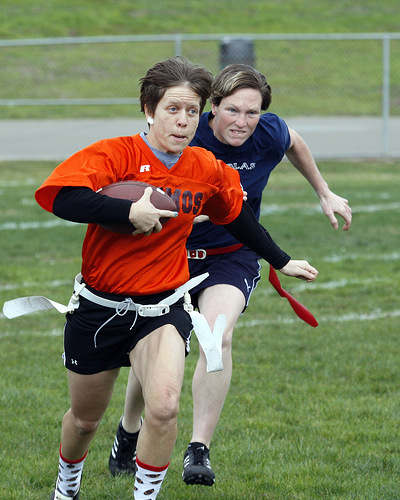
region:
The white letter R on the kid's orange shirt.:
[135, 162, 154, 170]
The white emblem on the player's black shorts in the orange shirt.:
[64, 354, 81, 368]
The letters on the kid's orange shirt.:
[155, 184, 209, 213]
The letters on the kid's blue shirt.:
[222, 164, 260, 172]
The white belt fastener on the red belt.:
[187, 246, 205, 261]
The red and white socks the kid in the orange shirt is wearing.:
[50, 439, 172, 499]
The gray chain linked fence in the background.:
[10, 37, 399, 126]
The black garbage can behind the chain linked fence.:
[209, 32, 273, 76]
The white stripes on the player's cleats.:
[107, 431, 215, 471]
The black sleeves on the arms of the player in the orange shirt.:
[53, 160, 283, 271]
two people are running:
[52, 62, 294, 498]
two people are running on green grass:
[11, 55, 378, 499]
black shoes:
[110, 397, 230, 491]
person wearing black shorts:
[45, 61, 255, 499]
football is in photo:
[80, 170, 183, 239]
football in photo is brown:
[90, 178, 186, 240]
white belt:
[11, 271, 219, 330]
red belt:
[187, 240, 328, 346]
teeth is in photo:
[226, 125, 247, 137]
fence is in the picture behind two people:
[3, 36, 399, 378]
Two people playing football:
[45, 41, 346, 461]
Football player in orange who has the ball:
[60, 52, 216, 344]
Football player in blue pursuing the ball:
[204, 44, 264, 272]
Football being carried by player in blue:
[84, 159, 189, 225]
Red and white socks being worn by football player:
[37, 442, 195, 496]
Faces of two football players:
[145, 85, 281, 142]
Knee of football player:
[147, 379, 181, 436]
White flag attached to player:
[183, 291, 233, 371]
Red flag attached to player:
[244, 244, 332, 329]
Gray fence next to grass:
[31, 31, 132, 99]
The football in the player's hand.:
[89, 178, 181, 230]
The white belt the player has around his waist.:
[73, 269, 201, 318]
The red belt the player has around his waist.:
[180, 241, 249, 261]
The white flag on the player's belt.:
[190, 310, 236, 370]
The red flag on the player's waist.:
[260, 257, 330, 331]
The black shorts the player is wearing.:
[58, 295, 204, 363]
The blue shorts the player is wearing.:
[183, 252, 267, 330]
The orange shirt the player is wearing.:
[66, 133, 227, 303]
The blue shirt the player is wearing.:
[183, 106, 280, 246]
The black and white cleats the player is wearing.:
[97, 419, 238, 485]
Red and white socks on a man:
[38, 439, 196, 499]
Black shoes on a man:
[106, 402, 238, 492]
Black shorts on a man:
[45, 267, 221, 376]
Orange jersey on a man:
[71, 128, 253, 307]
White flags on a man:
[22, 266, 264, 404]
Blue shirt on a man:
[170, 89, 320, 311]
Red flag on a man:
[192, 239, 360, 343]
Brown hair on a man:
[126, 53, 215, 166]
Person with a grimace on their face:
[195, 57, 293, 183]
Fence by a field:
[31, 20, 251, 140]